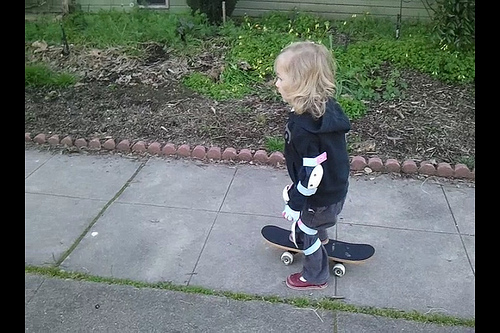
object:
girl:
[271, 41, 352, 290]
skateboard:
[259, 224, 373, 265]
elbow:
[297, 166, 324, 190]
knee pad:
[288, 221, 298, 252]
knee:
[288, 222, 318, 251]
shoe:
[285, 270, 327, 291]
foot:
[287, 272, 331, 289]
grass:
[25, 261, 55, 274]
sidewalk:
[26, 145, 475, 323]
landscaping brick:
[147, 142, 161, 155]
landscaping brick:
[163, 144, 176, 156]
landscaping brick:
[177, 145, 190, 157]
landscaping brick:
[192, 146, 207, 161]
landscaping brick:
[209, 148, 224, 162]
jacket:
[282, 113, 349, 206]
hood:
[295, 104, 349, 133]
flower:
[237, 35, 243, 39]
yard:
[25, 13, 478, 160]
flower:
[342, 21, 349, 25]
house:
[27, 0, 475, 20]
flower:
[434, 72, 437, 75]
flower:
[462, 75, 466, 79]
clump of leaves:
[33, 34, 231, 88]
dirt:
[35, 66, 476, 134]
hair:
[276, 42, 338, 115]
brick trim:
[25, 132, 274, 162]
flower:
[405, 53, 408, 57]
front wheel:
[279, 251, 293, 264]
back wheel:
[333, 264, 346, 277]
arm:
[283, 136, 324, 210]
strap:
[299, 150, 332, 166]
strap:
[293, 183, 318, 196]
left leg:
[287, 199, 335, 288]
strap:
[295, 219, 316, 234]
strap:
[302, 239, 322, 256]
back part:
[349, 245, 376, 260]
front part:
[261, 224, 281, 243]